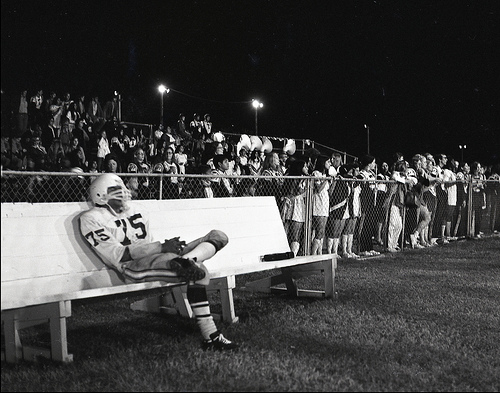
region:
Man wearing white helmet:
[89, 173, 132, 211]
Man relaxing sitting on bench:
[76, 172, 241, 354]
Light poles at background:
[155, 82, 167, 121]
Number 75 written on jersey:
[81, 214, 153, 244]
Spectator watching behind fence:
[289, 152, 489, 244]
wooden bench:
[0, 200, 79, 364]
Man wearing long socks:
[185, 285, 215, 337]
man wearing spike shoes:
[168, 257, 205, 279]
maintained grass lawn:
[257, 304, 399, 368]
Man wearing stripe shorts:
[122, 255, 171, 278]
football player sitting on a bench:
[78, 171, 244, 348]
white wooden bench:
[2, 193, 341, 363]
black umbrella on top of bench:
[261, 251, 296, 263]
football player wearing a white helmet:
[89, 172, 131, 209]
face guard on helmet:
[101, 188, 131, 203]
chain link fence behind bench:
[1, 170, 499, 257]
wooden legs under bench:
[218, 278, 240, 325]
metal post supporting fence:
[304, 178, 314, 251]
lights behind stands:
[157, 85, 172, 125]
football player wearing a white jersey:
[80, 203, 160, 273]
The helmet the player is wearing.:
[91, 175, 130, 200]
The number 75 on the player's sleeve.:
[87, 228, 115, 245]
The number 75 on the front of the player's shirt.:
[108, 212, 145, 243]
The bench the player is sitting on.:
[0, 201, 332, 357]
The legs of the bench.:
[5, 268, 335, 367]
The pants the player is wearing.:
[122, 254, 209, 284]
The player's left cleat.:
[198, 329, 236, 351]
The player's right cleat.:
[167, 259, 206, 279]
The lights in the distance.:
[148, 79, 472, 149]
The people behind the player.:
[32, 97, 497, 233]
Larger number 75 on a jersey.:
[111, 215, 148, 244]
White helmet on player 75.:
[88, 170, 131, 207]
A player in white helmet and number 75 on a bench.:
[76, 173, 241, 350]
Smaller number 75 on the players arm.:
[82, 227, 112, 246]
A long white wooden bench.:
[1, 194, 338, 361]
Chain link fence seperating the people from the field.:
[1, 168, 498, 256]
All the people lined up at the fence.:
[286, 153, 498, 256]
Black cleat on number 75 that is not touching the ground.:
[166, 258, 205, 282]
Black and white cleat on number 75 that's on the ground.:
[200, 330, 243, 353]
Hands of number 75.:
[160, 235, 190, 254]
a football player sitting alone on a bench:
[74, 170, 240, 355]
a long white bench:
[0, 192, 338, 359]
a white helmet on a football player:
[86, 170, 137, 213]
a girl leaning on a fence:
[284, 155, 310, 255]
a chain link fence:
[0, 168, 496, 264]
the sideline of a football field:
[1, 235, 498, 392]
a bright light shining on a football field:
[155, 82, 171, 97]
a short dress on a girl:
[283, 173, 309, 224]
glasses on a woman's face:
[162, 149, 175, 157]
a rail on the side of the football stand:
[305, 138, 361, 169]